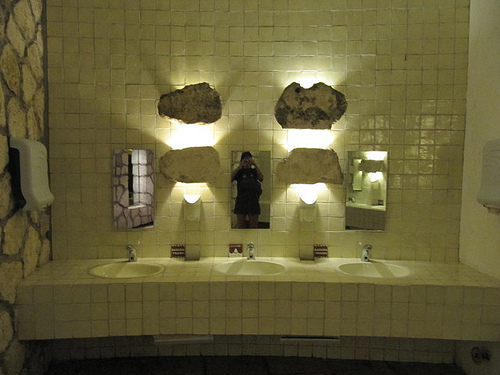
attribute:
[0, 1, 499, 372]
bathroom — public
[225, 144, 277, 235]
mirror — small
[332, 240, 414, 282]
sink — clean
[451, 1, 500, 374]
wall — stucco, white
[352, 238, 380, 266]
faucet — silver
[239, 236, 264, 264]
faucet — silver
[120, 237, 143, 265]
faucet — silver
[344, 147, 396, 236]
mirror — small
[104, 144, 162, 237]
mirror — small